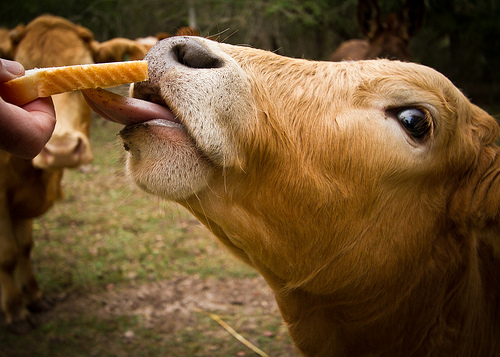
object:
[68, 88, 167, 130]
tongue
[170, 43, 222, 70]
nostril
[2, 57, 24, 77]
fingernail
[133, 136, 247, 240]
whiskers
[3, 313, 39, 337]
hoof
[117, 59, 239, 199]
mouth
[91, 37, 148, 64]
ear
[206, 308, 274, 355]
straw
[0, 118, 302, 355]
ground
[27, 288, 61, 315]
hooves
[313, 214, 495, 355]
brown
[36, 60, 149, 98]
edge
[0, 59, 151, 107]
bread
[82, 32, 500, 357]
animal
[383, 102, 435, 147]
eye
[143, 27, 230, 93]
nose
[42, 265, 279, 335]
dirt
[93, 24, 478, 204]
face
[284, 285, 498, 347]
neck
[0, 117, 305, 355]
grass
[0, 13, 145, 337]
animal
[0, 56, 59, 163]
hand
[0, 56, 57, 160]
person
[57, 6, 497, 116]
trees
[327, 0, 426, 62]
animal